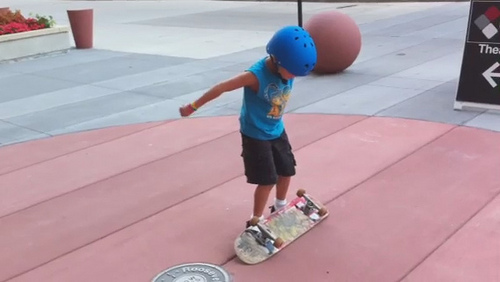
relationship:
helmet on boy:
[267, 23, 325, 72] [161, 20, 331, 234]